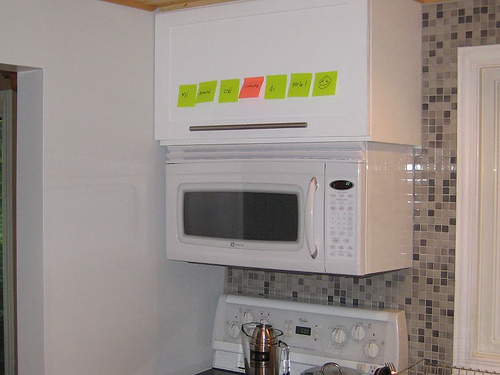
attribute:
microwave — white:
[165, 147, 415, 273]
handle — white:
[306, 180, 320, 257]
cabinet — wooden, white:
[147, 10, 424, 147]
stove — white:
[209, 295, 405, 375]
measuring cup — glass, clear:
[242, 322, 294, 371]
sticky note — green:
[198, 82, 216, 103]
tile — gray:
[410, 7, 454, 374]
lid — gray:
[301, 363, 356, 374]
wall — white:
[2, 6, 182, 375]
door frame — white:
[464, 48, 495, 361]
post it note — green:
[222, 78, 239, 101]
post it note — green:
[267, 76, 285, 101]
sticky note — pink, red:
[243, 78, 262, 98]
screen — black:
[295, 326, 314, 336]